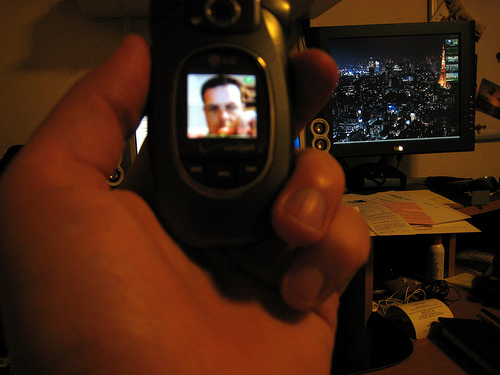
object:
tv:
[300, 24, 477, 157]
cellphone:
[145, 0, 291, 248]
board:
[341, 185, 500, 216]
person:
[0, 34, 368, 375]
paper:
[378, 200, 434, 225]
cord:
[377, 298, 403, 308]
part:
[187, 74, 257, 111]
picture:
[186, 72, 258, 139]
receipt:
[356, 202, 415, 236]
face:
[206, 98, 242, 134]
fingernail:
[284, 186, 328, 232]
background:
[310, 1, 499, 372]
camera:
[205, 3, 240, 27]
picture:
[300, 34, 461, 142]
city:
[334, 33, 458, 143]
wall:
[0, 0, 119, 145]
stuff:
[349, 315, 414, 372]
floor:
[349, 299, 498, 374]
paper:
[387, 298, 454, 340]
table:
[337, 200, 500, 334]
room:
[0, 0, 500, 372]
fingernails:
[281, 267, 324, 309]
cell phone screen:
[185, 72, 259, 138]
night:
[337, 43, 442, 75]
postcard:
[473, 78, 500, 120]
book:
[438, 317, 499, 368]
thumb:
[0, 34, 150, 188]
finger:
[272, 149, 347, 243]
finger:
[278, 203, 371, 309]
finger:
[288, 49, 337, 140]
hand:
[0, 33, 366, 375]